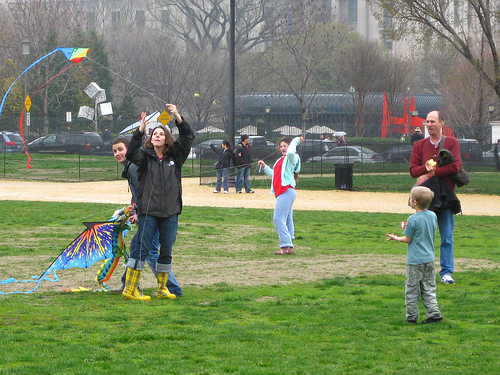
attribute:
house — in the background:
[228, 90, 449, 132]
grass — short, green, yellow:
[235, 331, 301, 374]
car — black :
[25, 128, 100, 158]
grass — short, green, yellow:
[1, 200, 498, 373]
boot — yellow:
[119, 266, 151, 300]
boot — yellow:
[153, 271, 178, 300]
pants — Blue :
[272, 185, 299, 248]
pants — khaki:
[402, 257, 440, 317]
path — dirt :
[0, 176, 497, 216]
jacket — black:
[123, 119, 196, 222]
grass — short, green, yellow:
[101, 297, 167, 374]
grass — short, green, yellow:
[325, 305, 392, 372]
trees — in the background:
[163, 18, 353, 122]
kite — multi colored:
[45, 40, 104, 70]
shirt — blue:
[401, 209, 436, 264]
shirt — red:
[407, 105, 465, 287]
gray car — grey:
[310, 141, 376, 163]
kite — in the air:
[28, 40, 116, 100]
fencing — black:
[4, 141, 109, 178]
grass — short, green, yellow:
[180, 312, 420, 374]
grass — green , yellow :
[237, 253, 371, 373]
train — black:
[344, 86, 367, 139]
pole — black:
[228, 1, 234, 157]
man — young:
[110, 138, 184, 300]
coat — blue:
[256, 136, 309, 194]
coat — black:
[357, 76, 496, 218]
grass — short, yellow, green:
[241, 289, 364, 348]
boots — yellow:
[123, 273, 160, 316]